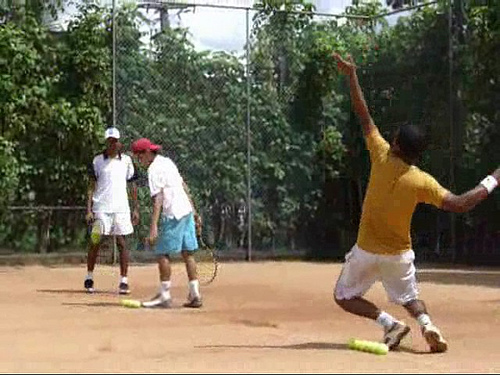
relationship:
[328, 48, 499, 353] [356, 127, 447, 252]
man wearing shirt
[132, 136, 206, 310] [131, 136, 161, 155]
man wearing cap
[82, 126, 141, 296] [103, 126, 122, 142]
man wearing cap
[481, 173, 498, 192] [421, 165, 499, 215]
sweat band on arm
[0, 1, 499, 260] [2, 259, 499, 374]
fence around tennis court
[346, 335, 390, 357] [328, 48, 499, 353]
tennis balls next to man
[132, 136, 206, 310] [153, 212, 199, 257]
man wearing shorts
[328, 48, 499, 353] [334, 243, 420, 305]
man wearing shorts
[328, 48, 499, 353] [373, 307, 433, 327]
man wearing socks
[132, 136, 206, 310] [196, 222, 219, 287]
man holding tennis racket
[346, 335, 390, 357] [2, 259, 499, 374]
tennis balls on tennis court